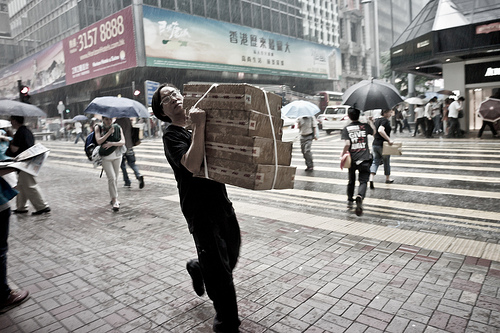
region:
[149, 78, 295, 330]
person carrying boxes awarkdly down the street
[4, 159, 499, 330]
sidewalk made or bricks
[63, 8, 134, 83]
white numbers and writing on maroon sign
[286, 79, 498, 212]
several people usin umbrellas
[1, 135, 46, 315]
someone reading a paper on the street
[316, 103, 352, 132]
white car driving down the street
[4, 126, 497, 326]
street and road is wet from rain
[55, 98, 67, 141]
street sign on a pole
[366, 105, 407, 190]
woman holding a package as she crosses street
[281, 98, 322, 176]
man with a white umbrella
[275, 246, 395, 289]
bricks on the sidewalk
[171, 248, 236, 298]
man's foot off the ground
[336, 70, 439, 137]
large open black umbrella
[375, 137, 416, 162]
large envelope in woman's hand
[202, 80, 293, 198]
white string around brown boxes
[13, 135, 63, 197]
person holding open newspaper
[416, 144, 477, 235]
broad white lines in the road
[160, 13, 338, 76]
large white sign on front of building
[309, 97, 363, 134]
white car on street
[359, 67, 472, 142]
people walking on the sidewalk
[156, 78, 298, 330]
a man carrying boxes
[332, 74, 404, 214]
a man with umbrella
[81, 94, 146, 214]
a woman with umbrella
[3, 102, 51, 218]
a man with umbrella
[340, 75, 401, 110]
an open black umbrella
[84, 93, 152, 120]
an open black umbrella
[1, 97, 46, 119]
an open black umbrella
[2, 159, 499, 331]
a brick paved sidewalk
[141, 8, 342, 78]
a large banner advertisement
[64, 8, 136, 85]
a large banner advertisement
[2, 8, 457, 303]
a picture of a city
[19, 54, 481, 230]
there is a lot of activity on the street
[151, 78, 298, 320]
this man is carrying boxes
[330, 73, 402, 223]
these people are walking fast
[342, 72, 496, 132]
most of these people have umbrellas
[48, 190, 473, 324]
this sidewalk is made of brick pavers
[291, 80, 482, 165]
people trying to avoid the rain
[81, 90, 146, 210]
an umbrella is covering the lady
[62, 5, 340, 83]
advertisements on a building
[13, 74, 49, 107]
a traffic light in the scene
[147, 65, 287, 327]
person carrying boxes in road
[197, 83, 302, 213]
stack of four boxes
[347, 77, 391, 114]
umbrella in person's hand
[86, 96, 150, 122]
umbrella in person's hand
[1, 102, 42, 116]
umbrella in person's hand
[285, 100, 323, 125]
umbrella in person's hand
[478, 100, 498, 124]
umbrella in person's hand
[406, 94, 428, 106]
umbrella in person's hand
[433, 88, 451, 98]
umbrella in person's hand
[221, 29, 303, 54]
characters on the billboard